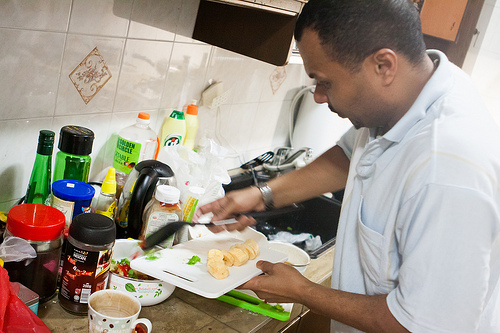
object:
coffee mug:
[86, 289, 154, 333]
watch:
[256, 181, 276, 210]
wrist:
[255, 182, 279, 212]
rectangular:
[129, 232, 289, 299]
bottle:
[99, 111, 157, 197]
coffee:
[57, 212, 117, 316]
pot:
[114, 160, 183, 238]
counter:
[0, 186, 346, 333]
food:
[205, 239, 260, 280]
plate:
[128, 232, 288, 299]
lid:
[68, 213, 117, 245]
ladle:
[142, 207, 295, 250]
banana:
[208, 260, 230, 279]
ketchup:
[140, 185, 182, 245]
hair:
[287, 1, 429, 70]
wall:
[132, 40, 190, 93]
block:
[229, 248, 249, 267]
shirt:
[326, 46, 499, 332]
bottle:
[141, 185, 182, 247]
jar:
[58, 213, 118, 317]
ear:
[373, 48, 400, 86]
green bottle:
[26, 130, 55, 205]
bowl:
[109, 269, 177, 306]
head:
[288, 0, 432, 132]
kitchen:
[0, 0, 500, 333]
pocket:
[357, 197, 390, 285]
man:
[184, 0, 499, 333]